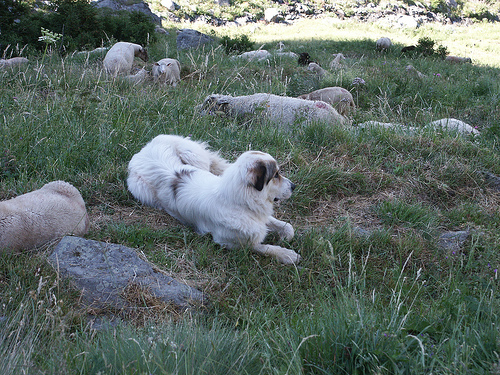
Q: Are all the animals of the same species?
A: No, there are both sheep and dogs.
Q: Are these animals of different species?
A: Yes, they are sheep and dogs.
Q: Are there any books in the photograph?
A: No, there are no books.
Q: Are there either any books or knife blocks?
A: No, there are no books or knife blocks.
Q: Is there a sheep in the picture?
A: Yes, there is a sheep.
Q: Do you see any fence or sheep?
A: Yes, there is a sheep.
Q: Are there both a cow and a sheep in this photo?
A: No, there is a sheep but no cows.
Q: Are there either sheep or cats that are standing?
A: Yes, the sheep is standing.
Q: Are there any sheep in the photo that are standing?
A: Yes, there is a sheep that is standing.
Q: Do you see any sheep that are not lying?
A: Yes, there is a sheep that is standing .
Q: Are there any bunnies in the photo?
A: No, there are no bunnies.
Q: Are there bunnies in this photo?
A: No, there are no bunnies.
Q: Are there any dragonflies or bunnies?
A: No, there are no bunnies or dragonflies.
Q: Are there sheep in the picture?
A: Yes, there is a sheep.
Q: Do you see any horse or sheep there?
A: Yes, there is a sheep.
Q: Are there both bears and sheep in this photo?
A: No, there is a sheep but no bears.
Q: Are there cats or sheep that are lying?
A: Yes, the sheep is lying.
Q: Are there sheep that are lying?
A: Yes, there is a sheep that is lying.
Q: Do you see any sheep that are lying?
A: Yes, there is a sheep that is lying.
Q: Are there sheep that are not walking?
A: Yes, there is a sheep that is lying.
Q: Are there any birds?
A: No, there are no birds.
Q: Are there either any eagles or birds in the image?
A: No, there are no birds or eagles.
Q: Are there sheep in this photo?
A: Yes, there is a sheep.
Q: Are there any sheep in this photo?
A: Yes, there is a sheep.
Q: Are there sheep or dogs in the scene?
A: Yes, there is a sheep.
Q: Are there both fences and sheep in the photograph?
A: No, there is a sheep but no fences.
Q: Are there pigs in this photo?
A: No, there are no pigs.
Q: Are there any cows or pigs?
A: No, there are no pigs or cows.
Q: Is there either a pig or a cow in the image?
A: No, there are no pigs or cows.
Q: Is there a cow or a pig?
A: No, there are no pigs or cows.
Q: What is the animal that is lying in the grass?
A: The animal is a sheep.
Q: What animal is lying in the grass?
A: The animal is a sheep.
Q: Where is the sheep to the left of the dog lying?
A: The sheep is lying in the grass.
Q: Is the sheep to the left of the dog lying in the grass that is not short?
A: Yes, the sheep is lying in the grass.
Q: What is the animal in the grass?
A: The animal is a sheep.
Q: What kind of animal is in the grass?
A: The animal is a sheep.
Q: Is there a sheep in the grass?
A: Yes, there is a sheep in the grass.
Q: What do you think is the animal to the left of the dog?
A: The animal is a sheep.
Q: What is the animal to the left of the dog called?
A: The animal is a sheep.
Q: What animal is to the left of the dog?
A: The animal is a sheep.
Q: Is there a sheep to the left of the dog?
A: Yes, there is a sheep to the left of the dog.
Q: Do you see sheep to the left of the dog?
A: Yes, there is a sheep to the left of the dog.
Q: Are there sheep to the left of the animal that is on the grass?
A: Yes, there is a sheep to the left of the dog.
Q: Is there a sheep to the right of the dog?
A: No, the sheep is to the left of the dog.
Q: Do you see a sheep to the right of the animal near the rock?
A: No, the sheep is to the left of the dog.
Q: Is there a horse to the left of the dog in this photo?
A: No, there is a sheep to the left of the dog.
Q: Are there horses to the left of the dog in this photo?
A: No, there is a sheep to the left of the dog.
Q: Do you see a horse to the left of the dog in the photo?
A: No, there is a sheep to the left of the dog.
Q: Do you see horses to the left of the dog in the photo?
A: No, there is a sheep to the left of the dog.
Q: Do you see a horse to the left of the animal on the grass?
A: No, there is a sheep to the left of the dog.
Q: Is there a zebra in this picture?
A: No, there are no zebras.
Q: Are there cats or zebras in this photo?
A: No, there are no zebras or cats.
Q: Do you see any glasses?
A: No, there are no glasses.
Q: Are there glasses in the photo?
A: No, there are no glasses.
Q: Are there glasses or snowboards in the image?
A: No, there are no glasses or snowboards.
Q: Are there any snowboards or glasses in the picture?
A: No, there are no glasses or snowboards.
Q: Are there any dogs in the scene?
A: Yes, there is a dog.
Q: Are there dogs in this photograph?
A: Yes, there is a dog.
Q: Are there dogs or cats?
A: Yes, there is a dog.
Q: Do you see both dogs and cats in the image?
A: No, there is a dog but no cats.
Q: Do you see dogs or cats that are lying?
A: Yes, the dog is lying.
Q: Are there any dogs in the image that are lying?
A: Yes, there is a dog that is lying.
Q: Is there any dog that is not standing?
A: Yes, there is a dog that is lying.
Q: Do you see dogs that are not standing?
A: Yes, there is a dog that is lying .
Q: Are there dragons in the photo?
A: No, there are no dragons.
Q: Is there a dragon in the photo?
A: No, there are no dragons.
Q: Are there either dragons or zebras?
A: No, there are no dragons or zebras.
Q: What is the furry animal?
A: The animal is a dog.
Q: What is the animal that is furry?
A: The animal is a dog.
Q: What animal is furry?
A: The animal is a dog.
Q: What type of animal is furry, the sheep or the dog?
A: The dog is furry.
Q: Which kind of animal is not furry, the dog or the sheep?
A: The sheep is not furry.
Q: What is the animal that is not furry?
A: The animal is a sheep.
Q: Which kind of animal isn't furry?
A: The animal is a sheep.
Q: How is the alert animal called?
A: The animal is a dog.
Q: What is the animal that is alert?
A: The animal is a dog.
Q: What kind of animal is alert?
A: The animal is a dog.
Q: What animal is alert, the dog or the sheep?
A: The dog is alert.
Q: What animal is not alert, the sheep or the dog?
A: The sheep is not alert.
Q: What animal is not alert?
A: The animal is a sheep.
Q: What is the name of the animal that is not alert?
A: The animal is a sheep.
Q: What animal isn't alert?
A: The animal is a sheep.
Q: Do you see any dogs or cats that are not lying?
A: No, there is a dog but it is lying.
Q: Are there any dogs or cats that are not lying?
A: No, there is a dog but it is lying.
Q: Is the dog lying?
A: Yes, the dog is lying.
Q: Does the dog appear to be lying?
A: Yes, the dog is lying.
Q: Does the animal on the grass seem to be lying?
A: Yes, the dog is lying.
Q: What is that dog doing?
A: The dog is lying.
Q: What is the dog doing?
A: The dog is lying.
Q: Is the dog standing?
A: No, the dog is lying.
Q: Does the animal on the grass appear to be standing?
A: No, the dog is lying.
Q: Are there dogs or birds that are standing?
A: No, there is a dog but it is lying.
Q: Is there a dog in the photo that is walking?
A: No, there is a dog but it is lying.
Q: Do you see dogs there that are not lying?
A: No, there is a dog but it is lying.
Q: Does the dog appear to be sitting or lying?
A: The dog is lying.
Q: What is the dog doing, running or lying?
A: The dog is lying.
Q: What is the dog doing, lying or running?
A: The dog is lying.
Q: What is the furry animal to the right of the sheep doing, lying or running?
A: The dog is lying.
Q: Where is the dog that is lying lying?
A: The dog is lying in the grass.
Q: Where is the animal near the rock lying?
A: The dog is lying in the grass.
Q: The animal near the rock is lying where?
A: The dog is lying in the grass.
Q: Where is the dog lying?
A: The dog is lying in the grass.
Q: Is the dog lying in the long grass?
A: Yes, the dog is lying in the grass.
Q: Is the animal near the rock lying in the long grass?
A: Yes, the dog is lying in the grass.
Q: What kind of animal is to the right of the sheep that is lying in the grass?
A: The animal is a dog.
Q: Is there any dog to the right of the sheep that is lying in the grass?
A: Yes, there is a dog to the right of the sheep.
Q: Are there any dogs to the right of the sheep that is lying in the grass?
A: Yes, there is a dog to the right of the sheep.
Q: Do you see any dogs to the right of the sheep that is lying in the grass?
A: Yes, there is a dog to the right of the sheep.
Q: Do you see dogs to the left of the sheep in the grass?
A: No, the dog is to the right of the sheep.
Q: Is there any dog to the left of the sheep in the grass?
A: No, the dog is to the right of the sheep.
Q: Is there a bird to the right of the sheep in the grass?
A: No, there is a dog to the right of the sheep.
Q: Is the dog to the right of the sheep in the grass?
A: Yes, the dog is to the right of the sheep.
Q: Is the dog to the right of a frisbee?
A: No, the dog is to the right of the sheep.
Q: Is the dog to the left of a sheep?
A: No, the dog is to the right of a sheep.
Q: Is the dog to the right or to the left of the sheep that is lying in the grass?
A: The dog is to the right of the sheep.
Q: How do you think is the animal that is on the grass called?
A: The animal is a dog.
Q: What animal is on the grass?
A: The animal is a dog.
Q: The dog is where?
A: The dog is on the grass.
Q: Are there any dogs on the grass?
A: Yes, there is a dog on the grass.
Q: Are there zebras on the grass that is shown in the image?
A: No, there is a dog on the grass.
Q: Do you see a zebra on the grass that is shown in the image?
A: No, there is a dog on the grass.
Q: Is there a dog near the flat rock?
A: Yes, there is a dog near the rock.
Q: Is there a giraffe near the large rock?
A: No, there is a dog near the rock.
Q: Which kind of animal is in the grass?
A: The animal is a dog.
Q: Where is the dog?
A: The dog is in the grass.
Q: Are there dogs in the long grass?
A: Yes, there is a dog in the grass.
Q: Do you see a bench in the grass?
A: No, there is a dog in the grass.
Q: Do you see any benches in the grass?
A: No, there is a dog in the grass.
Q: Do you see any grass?
A: Yes, there is grass.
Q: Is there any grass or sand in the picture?
A: Yes, there is grass.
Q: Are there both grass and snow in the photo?
A: No, there is grass but no snow.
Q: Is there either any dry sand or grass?
A: Yes, there is dry grass.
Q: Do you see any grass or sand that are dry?
A: Yes, the grass is dry.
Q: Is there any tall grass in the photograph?
A: Yes, there is tall grass.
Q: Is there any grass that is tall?
A: Yes, there is grass that is tall.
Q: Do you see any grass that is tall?
A: Yes, there is grass that is tall.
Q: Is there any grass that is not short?
A: Yes, there is tall grass.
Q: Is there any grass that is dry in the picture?
A: Yes, there is dry grass.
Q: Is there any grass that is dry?
A: Yes, there is grass that is dry.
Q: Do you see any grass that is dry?
A: Yes, there is grass that is dry.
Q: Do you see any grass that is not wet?
A: Yes, there is dry grass.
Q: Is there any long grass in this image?
A: Yes, there is long grass.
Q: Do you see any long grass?
A: Yes, there is long grass.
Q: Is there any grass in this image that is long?
A: Yes, there is grass that is long.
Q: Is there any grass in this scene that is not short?
A: Yes, there is long grass.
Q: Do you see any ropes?
A: No, there are no ropes.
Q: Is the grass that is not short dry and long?
A: Yes, the grass is dry and long.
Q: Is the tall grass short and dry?
A: No, the grass is dry but long.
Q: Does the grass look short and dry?
A: No, the grass is dry but tall.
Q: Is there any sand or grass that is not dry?
A: No, there is grass but it is dry.